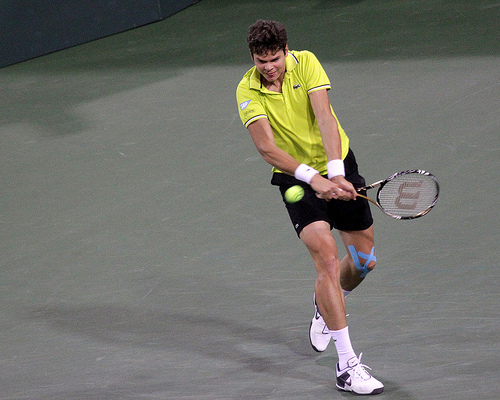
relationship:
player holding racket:
[231, 17, 310, 113] [322, 171, 438, 243]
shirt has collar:
[227, 78, 343, 168] [246, 67, 305, 104]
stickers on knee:
[347, 242, 371, 284] [345, 238, 382, 293]